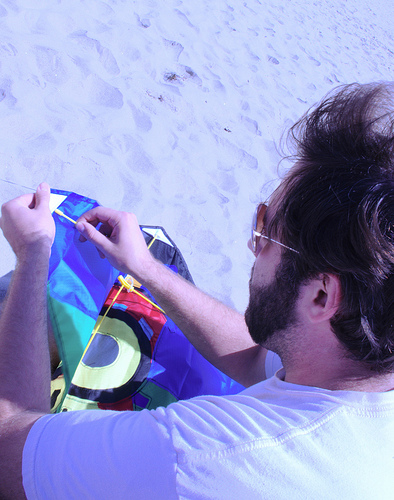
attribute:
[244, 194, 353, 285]
glasses — rose, gold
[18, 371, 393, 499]
shirt — seamed, white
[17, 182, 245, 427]
kite — blue, colorful, looped, multi-colored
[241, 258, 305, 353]
beard — brown, thick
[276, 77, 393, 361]
hair — brown, dark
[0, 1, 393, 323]
sand — marked, small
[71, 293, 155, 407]
logo — blue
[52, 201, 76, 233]
piece — yellow